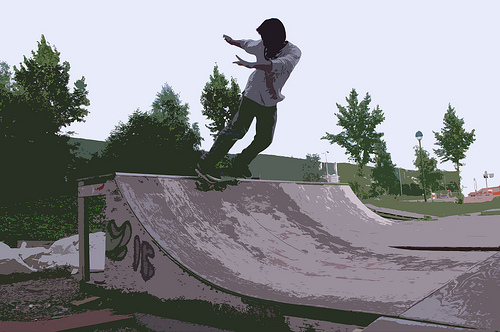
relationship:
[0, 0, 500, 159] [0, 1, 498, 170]
cloud in blue sky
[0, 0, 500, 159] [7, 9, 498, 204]
cloud in sky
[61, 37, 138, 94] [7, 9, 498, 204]
cloud in sky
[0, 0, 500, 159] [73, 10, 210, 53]
cloud in blue sky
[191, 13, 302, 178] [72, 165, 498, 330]
man on ramp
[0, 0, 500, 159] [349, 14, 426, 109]
cloud in sky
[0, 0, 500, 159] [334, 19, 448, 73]
cloud in sky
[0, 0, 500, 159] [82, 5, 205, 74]
cloud in sky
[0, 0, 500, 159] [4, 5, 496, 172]
cloud in sky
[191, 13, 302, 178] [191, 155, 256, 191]
man on skateboard